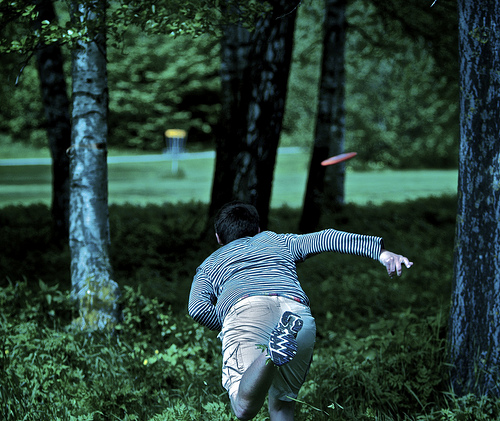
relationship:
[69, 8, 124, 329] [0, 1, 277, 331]
trunk on tree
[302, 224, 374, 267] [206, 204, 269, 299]
arm on person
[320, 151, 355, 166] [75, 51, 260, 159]
frisbee in sky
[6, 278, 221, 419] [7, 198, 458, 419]
leaves on ground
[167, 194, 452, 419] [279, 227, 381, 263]
man with h arm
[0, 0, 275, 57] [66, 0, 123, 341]
leaves from tree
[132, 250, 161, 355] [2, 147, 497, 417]
plants on ground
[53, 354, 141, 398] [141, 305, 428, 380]
plants on ground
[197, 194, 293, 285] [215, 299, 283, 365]
man wearing shorts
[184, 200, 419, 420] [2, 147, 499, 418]
person in field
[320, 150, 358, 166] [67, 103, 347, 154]
frisbee in air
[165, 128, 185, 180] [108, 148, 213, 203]
disc gulf in field